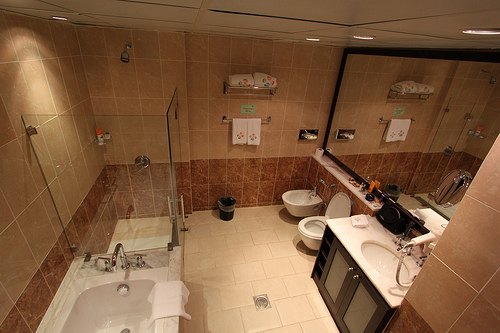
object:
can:
[216, 196, 235, 220]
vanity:
[312, 205, 426, 330]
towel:
[231, 118, 261, 145]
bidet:
[282, 189, 322, 217]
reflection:
[320, 53, 500, 230]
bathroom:
[0, 2, 498, 333]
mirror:
[322, 46, 495, 237]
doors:
[163, 88, 194, 246]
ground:
[317, 48, 498, 215]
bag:
[220, 196, 237, 206]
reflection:
[0, 31, 62, 122]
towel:
[226, 73, 255, 86]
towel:
[253, 71, 277, 87]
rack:
[222, 70, 276, 98]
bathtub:
[35, 244, 181, 333]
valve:
[91, 255, 115, 274]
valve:
[128, 252, 155, 268]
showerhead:
[118, 39, 131, 62]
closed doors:
[312, 240, 391, 333]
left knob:
[95, 252, 116, 274]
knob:
[132, 251, 152, 269]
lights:
[306, 34, 323, 43]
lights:
[348, 29, 378, 41]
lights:
[461, 23, 497, 36]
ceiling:
[0, 0, 493, 54]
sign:
[240, 103, 257, 115]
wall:
[78, 29, 318, 209]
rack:
[222, 116, 272, 123]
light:
[47, 14, 73, 22]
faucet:
[88, 241, 148, 273]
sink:
[339, 216, 426, 304]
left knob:
[392, 235, 408, 246]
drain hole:
[120, 327, 133, 333]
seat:
[296, 194, 351, 240]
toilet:
[285, 174, 354, 253]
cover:
[324, 189, 354, 221]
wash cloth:
[350, 212, 368, 228]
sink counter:
[325, 212, 423, 309]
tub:
[45, 245, 182, 333]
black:
[216, 195, 236, 221]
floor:
[185, 200, 343, 333]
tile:
[261, 258, 297, 279]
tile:
[230, 261, 266, 284]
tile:
[251, 230, 281, 245]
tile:
[198, 232, 226, 252]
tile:
[271, 295, 319, 327]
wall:
[0, 5, 115, 329]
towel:
[139, 278, 192, 324]